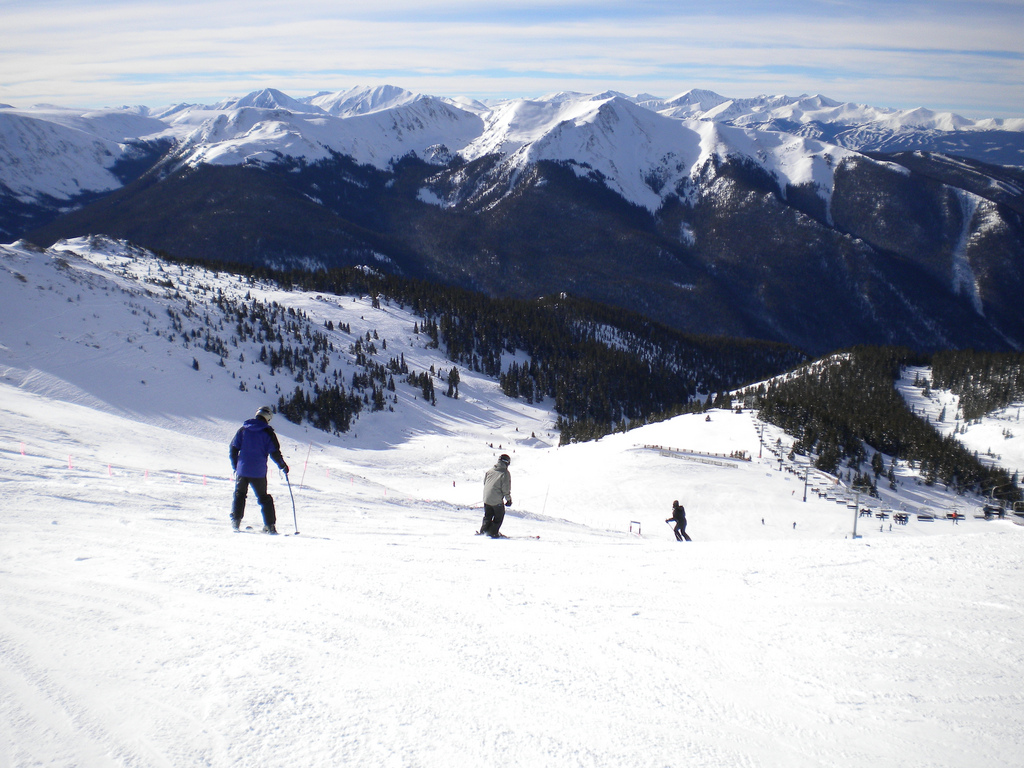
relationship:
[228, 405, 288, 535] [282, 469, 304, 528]
man holding ski pole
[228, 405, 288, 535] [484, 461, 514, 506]
man wearing coat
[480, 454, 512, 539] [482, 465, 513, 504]
man has jacket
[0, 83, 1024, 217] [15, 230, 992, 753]
snow on hill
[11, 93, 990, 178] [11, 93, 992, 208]
snow on cap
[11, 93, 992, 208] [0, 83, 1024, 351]
cap of mountain range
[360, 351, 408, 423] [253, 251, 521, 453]
trees on hill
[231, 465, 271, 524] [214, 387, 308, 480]
legs of a man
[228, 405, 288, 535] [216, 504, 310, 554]
man on skis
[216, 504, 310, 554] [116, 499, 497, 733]
skis in snow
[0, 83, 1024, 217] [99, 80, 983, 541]
snow on top of mountains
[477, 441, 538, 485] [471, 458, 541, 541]
man wearing a coat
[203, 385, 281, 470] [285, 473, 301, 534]
man holding ski pole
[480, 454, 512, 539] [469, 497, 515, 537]
man wearing pants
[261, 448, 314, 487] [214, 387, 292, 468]
hand of a man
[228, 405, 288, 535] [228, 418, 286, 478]
man wearing a coat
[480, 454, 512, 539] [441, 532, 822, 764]
man standing on a hill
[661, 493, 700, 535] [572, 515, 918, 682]
person riding to ski slope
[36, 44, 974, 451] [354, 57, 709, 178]
mountain range covered in snow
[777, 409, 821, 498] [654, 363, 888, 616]
tree covered with snow filled hill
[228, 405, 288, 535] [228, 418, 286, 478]
man wearing coat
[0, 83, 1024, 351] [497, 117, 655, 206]
mountain range covered in snow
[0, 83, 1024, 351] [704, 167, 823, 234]
mountain range covered in trees